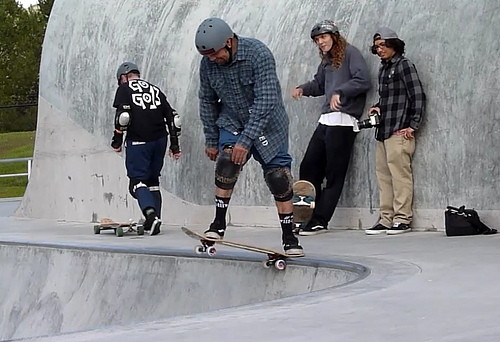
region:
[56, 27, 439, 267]
four men standing together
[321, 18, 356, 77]
a man with long hair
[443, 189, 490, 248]
a black bag on the ground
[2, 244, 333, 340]
a concrete skateboard ramp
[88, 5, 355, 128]
three men wearing helmets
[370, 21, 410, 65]
a man wearing a cap backwards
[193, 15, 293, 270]
a man on a skateboard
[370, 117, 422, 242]
a man wearing tan pants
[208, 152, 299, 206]
a man wearing knee pads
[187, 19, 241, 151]
a man looking down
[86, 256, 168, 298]
stains in the skate board ramp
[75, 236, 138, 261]
edge of the ramp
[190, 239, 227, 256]
white wheels under skate board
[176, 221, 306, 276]
large skate board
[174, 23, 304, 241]
man standing on skate board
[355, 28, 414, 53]
man's bushy short black hair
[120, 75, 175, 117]
white words at back of black shirt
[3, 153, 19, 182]
small white fence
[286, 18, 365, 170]
man leaning against wall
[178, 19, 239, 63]
blue helment with black band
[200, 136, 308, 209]
man is wearing knee pads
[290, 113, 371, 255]
the pants are black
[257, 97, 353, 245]
the pants are black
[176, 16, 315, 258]
the man on the skateboard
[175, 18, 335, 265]
the man at the edge of the drop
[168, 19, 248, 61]
the gray helmet on the head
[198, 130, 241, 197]
the man wearing kneepads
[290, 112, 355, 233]
the man with the black pants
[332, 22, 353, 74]
the man with the long curly hair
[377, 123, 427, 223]
the man wearing tan pants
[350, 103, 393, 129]
the man holding the camera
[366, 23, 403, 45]
the man wearing the cap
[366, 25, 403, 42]
the cap is gray